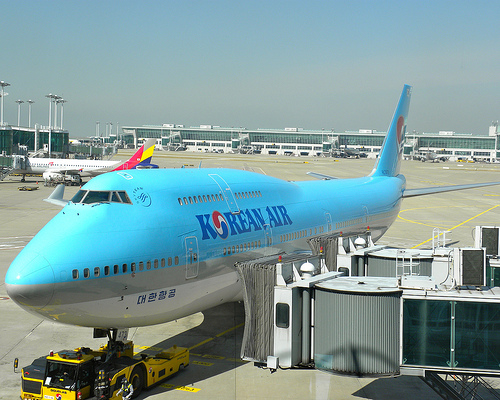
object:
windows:
[183, 197, 189, 205]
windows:
[83, 268, 90, 279]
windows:
[72, 269, 80, 280]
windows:
[177, 197, 183, 205]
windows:
[223, 248, 226, 256]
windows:
[94, 267, 101, 278]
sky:
[0, 0, 500, 139]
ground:
[0, 149, 500, 400]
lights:
[44, 93, 56, 99]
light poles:
[17, 101, 20, 126]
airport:
[0, 81, 500, 400]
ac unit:
[454, 245, 487, 291]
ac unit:
[474, 225, 500, 259]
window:
[258, 191, 263, 198]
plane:
[3, 83, 500, 330]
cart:
[19, 338, 190, 399]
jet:
[0, 138, 160, 183]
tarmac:
[0, 148, 500, 400]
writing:
[194, 205, 293, 240]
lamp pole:
[48, 97, 52, 159]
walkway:
[235, 250, 323, 365]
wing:
[42, 183, 71, 209]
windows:
[241, 191, 245, 198]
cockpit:
[69, 188, 134, 205]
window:
[188, 196, 194, 205]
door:
[184, 236, 199, 280]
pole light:
[53, 95, 60, 129]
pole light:
[57, 98, 68, 129]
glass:
[402, 299, 451, 368]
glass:
[454, 300, 500, 371]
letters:
[137, 294, 147, 305]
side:
[8, 210, 401, 330]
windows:
[168, 256, 173, 266]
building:
[134, 120, 499, 163]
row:
[72, 256, 180, 280]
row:
[222, 239, 262, 256]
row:
[234, 190, 263, 200]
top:
[3, 84, 414, 285]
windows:
[193, 195, 198, 204]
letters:
[194, 213, 217, 240]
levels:
[177, 193, 224, 206]